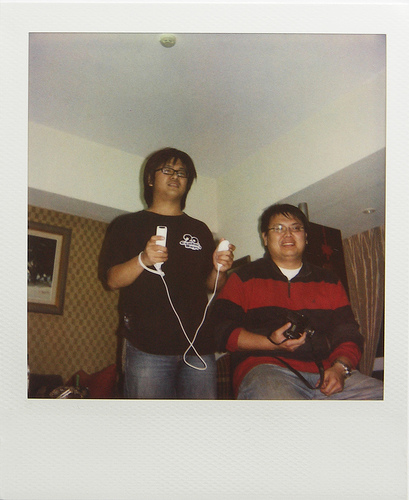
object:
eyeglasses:
[153, 167, 190, 178]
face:
[153, 157, 188, 195]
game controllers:
[216, 240, 232, 267]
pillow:
[65, 364, 116, 400]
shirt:
[96, 209, 215, 355]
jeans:
[236, 367, 384, 400]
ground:
[311, 131, 325, 156]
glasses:
[265, 222, 303, 234]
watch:
[331, 359, 351, 377]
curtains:
[341, 218, 384, 378]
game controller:
[155, 225, 168, 268]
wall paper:
[27, 205, 119, 374]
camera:
[281, 310, 316, 343]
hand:
[315, 365, 346, 397]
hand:
[270, 321, 307, 352]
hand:
[143, 235, 168, 266]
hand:
[212, 237, 236, 272]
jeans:
[125, 340, 220, 399]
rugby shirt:
[212, 258, 366, 399]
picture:
[26, 221, 71, 315]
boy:
[97, 145, 237, 401]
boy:
[209, 200, 383, 402]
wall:
[25, 72, 384, 400]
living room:
[28, 30, 384, 401]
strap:
[138, 250, 221, 372]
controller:
[138, 224, 232, 372]